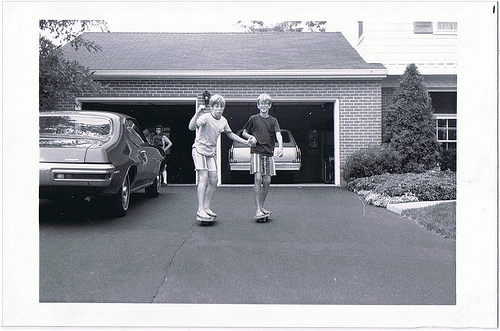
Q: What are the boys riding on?
A: Skateboards.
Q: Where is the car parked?
A: Driveway.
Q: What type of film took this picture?
A: Black and white.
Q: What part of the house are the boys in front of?
A: Garage.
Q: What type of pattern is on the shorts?
A: Stripe.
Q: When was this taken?
A: 70s.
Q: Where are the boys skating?
A: Driveway.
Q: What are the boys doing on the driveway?
A: Skateboarding.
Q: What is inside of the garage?
A: A vehicle.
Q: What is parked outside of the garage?
A: A car.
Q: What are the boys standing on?
A: Skateboards.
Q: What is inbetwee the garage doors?
A: A light.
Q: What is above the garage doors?
A: A rain gutter.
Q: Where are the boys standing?
A: In the driveway.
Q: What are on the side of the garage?
A: Bushes.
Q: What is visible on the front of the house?
A: A window.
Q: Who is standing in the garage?
A: A woman.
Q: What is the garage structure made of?
A: Bricks.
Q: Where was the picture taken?
A: A driveway.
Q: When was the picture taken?
A: Daytime.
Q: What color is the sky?
A: White.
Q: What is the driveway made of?
A: Tar.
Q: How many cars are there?
A: Two.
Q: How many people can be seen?
A: Three.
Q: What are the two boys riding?
A: Skateboards.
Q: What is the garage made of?
A: Brick.